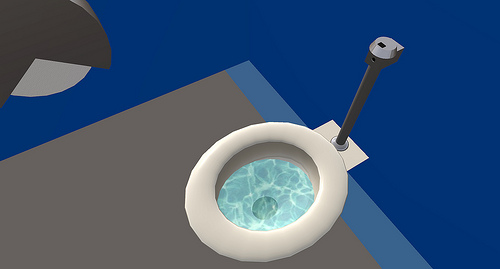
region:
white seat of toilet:
[184, 120, 348, 260]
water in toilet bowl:
[221, 159, 310, 229]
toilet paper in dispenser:
[0, 1, 109, 111]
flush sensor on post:
[335, 34, 403, 143]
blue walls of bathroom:
[0, 1, 498, 267]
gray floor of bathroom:
[1, 59, 431, 266]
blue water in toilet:
[235, 140, 301, 225]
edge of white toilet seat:
[179, 153, 228, 219]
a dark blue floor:
[411, 87, 491, 242]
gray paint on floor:
[58, 150, 140, 252]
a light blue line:
[227, 46, 288, 111]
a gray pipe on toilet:
[324, 33, 412, 144]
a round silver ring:
[326, 134, 354, 152]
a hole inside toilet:
[241, 190, 286, 224]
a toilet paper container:
[0, 2, 118, 104]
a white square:
[321, 105, 372, 177]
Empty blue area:
[279, 26, 324, 77]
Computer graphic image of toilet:
[188, 114, 343, 254]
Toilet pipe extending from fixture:
[342, 32, 399, 154]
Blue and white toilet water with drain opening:
[239, 179, 285, 220]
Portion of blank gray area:
[45, 163, 129, 237]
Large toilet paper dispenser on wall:
[5, 9, 110, 101]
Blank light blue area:
[365, 214, 392, 250]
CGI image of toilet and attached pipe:
[183, 38, 405, 263]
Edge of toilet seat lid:
[181, 157, 234, 256]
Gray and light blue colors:
[211, 67, 254, 117]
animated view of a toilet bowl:
[178, 120, 349, 251]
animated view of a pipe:
[333, 64, 378, 144]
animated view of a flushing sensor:
[367, 38, 392, 73]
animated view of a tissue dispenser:
[0, 0, 111, 115]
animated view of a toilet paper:
[9, 57, 93, 102]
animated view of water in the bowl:
[218, 157, 313, 223]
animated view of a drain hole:
[251, 193, 278, 221]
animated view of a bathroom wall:
[254, 6, 499, 264]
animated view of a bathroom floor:
[0, 63, 429, 266]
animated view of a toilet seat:
[183, 118, 348, 262]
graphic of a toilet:
[184, 34, 405, 261]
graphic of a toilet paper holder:
[0, 0, 111, 105]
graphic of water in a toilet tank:
[217, 155, 315, 229]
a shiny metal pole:
[336, 35, 406, 141]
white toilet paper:
[12, 58, 89, 96]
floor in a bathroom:
[0, 62, 432, 267]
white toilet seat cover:
[186, 117, 348, 262]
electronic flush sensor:
[364, 34, 405, 68]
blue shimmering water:
[215, 156, 315, 231]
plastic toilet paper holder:
[0, 0, 110, 104]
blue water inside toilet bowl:
[216, 156, 315, 231]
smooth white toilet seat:
[184, 120, 352, 261]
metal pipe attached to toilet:
[335, 34, 406, 146]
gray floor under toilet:
[0, 70, 376, 266]